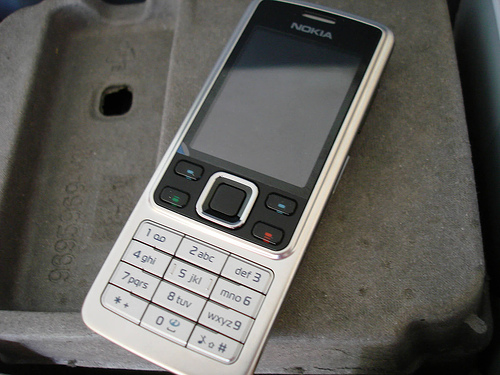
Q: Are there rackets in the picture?
A: No, there are no rackets.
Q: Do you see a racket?
A: No, there are no rackets.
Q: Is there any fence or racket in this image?
A: No, there are no rackets or fences.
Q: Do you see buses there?
A: No, there are no buses.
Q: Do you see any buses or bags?
A: No, there are no buses or bags.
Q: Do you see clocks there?
A: No, there are no clocks.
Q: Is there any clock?
A: No, there are no clocks.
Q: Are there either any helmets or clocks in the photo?
A: No, there are no clocks or helmets.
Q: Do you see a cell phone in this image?
A: Yes, there is a cell phone.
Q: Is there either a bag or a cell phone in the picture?
A: Yes, there is a cell phone.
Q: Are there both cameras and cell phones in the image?
A: No, there is a cell phone but no cameras.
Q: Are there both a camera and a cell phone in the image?
A: No, there is a cell phone but no cameras.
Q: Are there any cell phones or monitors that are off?
A: Yes, the cell phone is off.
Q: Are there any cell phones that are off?
A: Yes, there is a cell phone that is off.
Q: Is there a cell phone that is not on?
A: Yes, there is a cell phone that is off.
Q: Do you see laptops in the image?
A: No, there are no laptops.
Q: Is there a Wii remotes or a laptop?
A: No, there are no laptops or Wii controllers.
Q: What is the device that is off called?
A: The device is a cell phone.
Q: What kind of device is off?
A: The device is a cell phone.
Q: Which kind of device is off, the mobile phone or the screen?
A: The mobile phone is off.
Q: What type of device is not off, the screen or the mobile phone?
A: The screen is not off.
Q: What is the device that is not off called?
A: The device is a screen.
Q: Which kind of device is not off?
A: The device is a screen.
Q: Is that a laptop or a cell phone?
A: That is a cell phone.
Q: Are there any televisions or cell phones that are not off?
A: No, there is a cell phone but it is off.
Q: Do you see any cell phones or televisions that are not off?
A: No, there is a cell phone but it is off.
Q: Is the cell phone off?
A: Yes, the cell phone is off.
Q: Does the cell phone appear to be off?
A: Yes, the cell phone is off.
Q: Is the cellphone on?
A: No, the cellphone is off.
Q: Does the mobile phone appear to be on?
A: No, the mobile phone is off.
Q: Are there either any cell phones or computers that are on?
A: No, there is a cell phone but it is off.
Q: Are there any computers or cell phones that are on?
A: No, there is a cell phone but it is off.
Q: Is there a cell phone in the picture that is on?
A: No, there is a cell phone but it is off.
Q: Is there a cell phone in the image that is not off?
A: No, there is a cell phone but it is off.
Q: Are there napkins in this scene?
A: No, there are no napkins.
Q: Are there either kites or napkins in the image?
A: No, there are no napkins or kites.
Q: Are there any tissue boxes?
A: No, there are no tissue boxes.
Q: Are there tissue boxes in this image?
A: No, there are no tissue boxes.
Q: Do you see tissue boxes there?
A: No, there are no tissue boxes.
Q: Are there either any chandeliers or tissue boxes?
A: No, there are no tissue boxes or chandeliers.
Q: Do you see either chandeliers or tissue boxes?
A: No, there are no tissue boxes or chandeliers.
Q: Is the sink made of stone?
A: Yes, the sink is made of stone.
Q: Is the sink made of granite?
A: No, the sink is made of stone.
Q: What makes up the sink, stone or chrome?
A: The sink is made of stone.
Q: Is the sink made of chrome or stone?
A: The sink is made of stone.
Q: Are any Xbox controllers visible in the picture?
A: No, there are no Xbox controllers.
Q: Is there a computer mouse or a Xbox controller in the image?
A: No, there are no Xbox controllers or computer mice.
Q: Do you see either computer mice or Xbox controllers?
A: No, there are no Xbox controllers or computer mice.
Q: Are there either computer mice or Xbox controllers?
A: No, there are no Xbox controllers or computer mice.